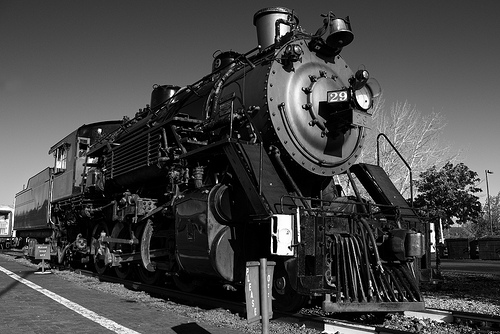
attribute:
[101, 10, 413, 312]
engine — antique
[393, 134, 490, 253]
tree — leafless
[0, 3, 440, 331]
locomotive — black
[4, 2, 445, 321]
train — black, vintage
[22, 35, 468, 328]
locomotive — black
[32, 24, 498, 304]
train — black, white, old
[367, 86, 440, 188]
tree — leafless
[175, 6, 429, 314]
engine — black, classic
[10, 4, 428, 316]
engine — old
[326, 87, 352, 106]
number — 29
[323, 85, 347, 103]
number — 29